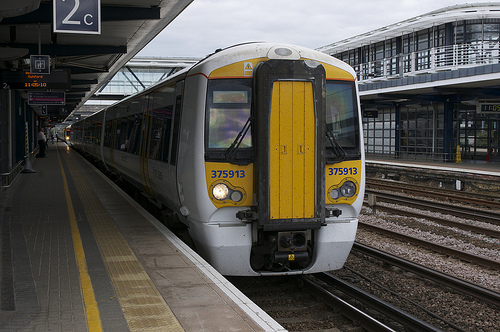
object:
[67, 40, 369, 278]
train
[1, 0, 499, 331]
station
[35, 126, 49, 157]
man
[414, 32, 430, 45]
windows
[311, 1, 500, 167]
building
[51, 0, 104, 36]
signs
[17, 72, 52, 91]
sign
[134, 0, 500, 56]
sky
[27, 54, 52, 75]
sign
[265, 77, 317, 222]
door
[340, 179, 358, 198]
headlights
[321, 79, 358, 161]
windshields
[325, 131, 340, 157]
wipes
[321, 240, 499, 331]
tracks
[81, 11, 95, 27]
lettering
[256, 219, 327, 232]
slats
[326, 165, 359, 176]
number 375913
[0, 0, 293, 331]
train depot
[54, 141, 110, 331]
stripe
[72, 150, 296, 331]
stripe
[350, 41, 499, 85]
balcony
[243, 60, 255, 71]
sign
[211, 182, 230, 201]
headlight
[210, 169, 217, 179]
numbers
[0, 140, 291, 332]
walkway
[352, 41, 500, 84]
railing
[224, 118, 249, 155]
wiper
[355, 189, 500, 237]
tracks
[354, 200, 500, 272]
tracks